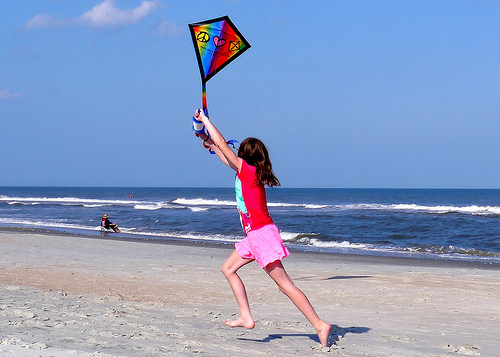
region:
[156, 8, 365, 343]
young girl on beach trying to fly a kite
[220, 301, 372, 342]
girl's shadow is on the sand below her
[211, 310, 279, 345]
one foot is in the air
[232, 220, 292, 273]
girl wearing pink shorts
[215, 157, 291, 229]
girl wearing red shirt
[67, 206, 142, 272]
person sitting in folding chair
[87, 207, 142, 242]
folding chair is in shallow water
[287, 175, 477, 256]
ocean in background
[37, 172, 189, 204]
water is calm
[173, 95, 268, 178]
girl holding kite string handle with two hands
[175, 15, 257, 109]
a beautiful sky in air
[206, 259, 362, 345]
legs of the cute girl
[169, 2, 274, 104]
a cute kite holding by girl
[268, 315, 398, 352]
shadow of the girl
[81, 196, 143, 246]
a man in the beach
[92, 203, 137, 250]
a man sitting near water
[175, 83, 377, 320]
a cute girl running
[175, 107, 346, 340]
a young girl running in beach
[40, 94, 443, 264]
a beautiful view of water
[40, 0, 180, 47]
white clouds in sky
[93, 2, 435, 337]
a girl flying a kite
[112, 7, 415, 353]
a young child flying a kite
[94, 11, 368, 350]
a child flying a kite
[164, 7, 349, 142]
a kite in the air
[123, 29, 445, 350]
a girl on the beach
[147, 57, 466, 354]
a young child on the beach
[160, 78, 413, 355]
a child on the beach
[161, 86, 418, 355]
young child running on beach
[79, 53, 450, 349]
child running on beach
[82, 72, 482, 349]
sand and water on beach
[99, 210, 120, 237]
person sitting on chair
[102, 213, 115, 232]
person wearing brown hat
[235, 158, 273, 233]
red cotton tee shirt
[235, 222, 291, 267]
light pink cotton shorts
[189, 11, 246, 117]
rainbow kite with tail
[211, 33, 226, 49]
hear design on kite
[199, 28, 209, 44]
peace sign on kite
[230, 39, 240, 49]
kite design on fabric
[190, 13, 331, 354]
girl flying rainbow kite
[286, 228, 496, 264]
small wave in ocean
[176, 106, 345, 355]
little girl running on a beach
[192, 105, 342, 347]
little girl in red shirt and pink shorts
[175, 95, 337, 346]
little girl playing with a colorful kite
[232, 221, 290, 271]
little girls pink shorts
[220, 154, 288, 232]
little girls red shirt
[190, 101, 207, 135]
spool of kite string the little girl is holding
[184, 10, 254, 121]
colorful kite making its way into the air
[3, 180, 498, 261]
ocean water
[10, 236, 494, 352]
sandy beach area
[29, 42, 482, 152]
beautiful blue sky